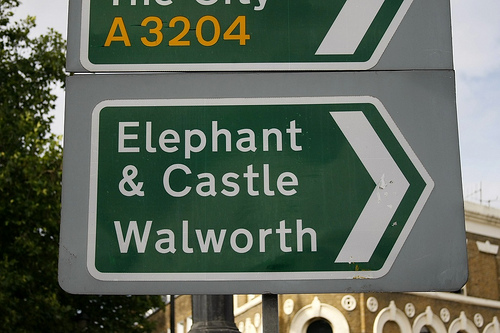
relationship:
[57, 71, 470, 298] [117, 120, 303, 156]
sign has letters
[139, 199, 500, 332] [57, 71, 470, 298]
building behind sign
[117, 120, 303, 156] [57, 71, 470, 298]
letters are on sign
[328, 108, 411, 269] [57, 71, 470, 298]
arrow on sign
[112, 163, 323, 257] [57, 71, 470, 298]
words are on sign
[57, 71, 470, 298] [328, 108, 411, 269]
sign has arrow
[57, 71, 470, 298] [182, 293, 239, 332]
sign attached to pole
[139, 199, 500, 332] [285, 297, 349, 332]
building has arch